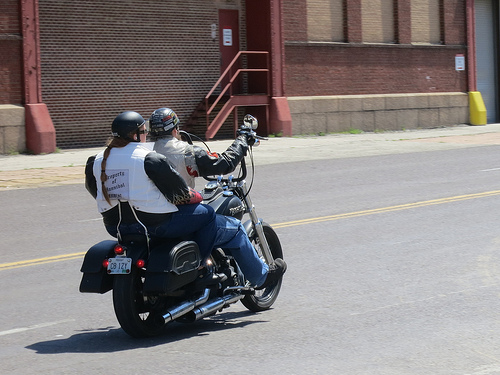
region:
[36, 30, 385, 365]
Two people on a motorcycle.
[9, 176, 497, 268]
Yellow line painted on street.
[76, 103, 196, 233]
A person with a long braid of hair.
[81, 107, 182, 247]
A person wearing a white vest.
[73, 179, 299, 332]
A black motorcycle.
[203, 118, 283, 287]
A pair of light colored jeans.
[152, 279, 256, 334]
Two silver mufflers on motorcycle.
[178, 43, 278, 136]
Set of stairs to building door.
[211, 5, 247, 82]
The door on the side of a building.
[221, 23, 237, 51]
White square sign on door.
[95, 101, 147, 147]
Woman with helmet on her head.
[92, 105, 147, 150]
Woman with black helmet on her head.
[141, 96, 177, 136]
Man with helmet on his head.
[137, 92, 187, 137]
Man with colorful helmet on his head.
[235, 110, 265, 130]
A man's hand with a glove on.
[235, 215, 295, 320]
A motorcycle tire on the street.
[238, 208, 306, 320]
A black motorcycle tire on the street.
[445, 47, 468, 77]
A sign on a building.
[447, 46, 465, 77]
A red and white sign on a building.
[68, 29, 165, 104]
A piece of a brick wall.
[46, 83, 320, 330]
two people on a black motorcycle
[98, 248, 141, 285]
a license plate on a motorcycle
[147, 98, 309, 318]
a man driving a motorcycle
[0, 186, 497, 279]
double yellow lines on the road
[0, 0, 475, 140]
a brick building on the left of the motorcyclists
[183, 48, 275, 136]
a staircase made of metal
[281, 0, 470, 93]
a rectangular sign on a brick building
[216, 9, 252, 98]
a red door with a rectangular sign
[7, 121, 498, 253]
a sidewalk next to the road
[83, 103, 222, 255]
two people wearing helmets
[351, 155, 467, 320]
a smooth grey street.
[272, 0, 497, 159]
a red brick building.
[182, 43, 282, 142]
a burgundy staircase.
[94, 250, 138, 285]
a white licence plate.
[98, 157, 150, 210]
a woman is wearing a white and black jacket.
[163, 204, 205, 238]
a woman is wearing blue jeans.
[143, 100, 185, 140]
a man is wearing a black yellow and red helmet.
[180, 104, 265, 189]
a man is wearing a black and red jacket.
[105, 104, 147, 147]
a woman is wearing a black helmet.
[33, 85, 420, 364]
a man is riding the woman on the motorcycle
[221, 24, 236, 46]
Delivery instructions posted on back door.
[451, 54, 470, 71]
No parking sign posted at delivery gate.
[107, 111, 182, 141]
Sun bouncing off black helmets.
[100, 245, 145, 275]
Three red lights and a license plate.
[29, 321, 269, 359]
Shadow under a motorcycle.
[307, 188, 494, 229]
Yellow street markings in middle of street.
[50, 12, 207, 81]
Red brick wall with white grout.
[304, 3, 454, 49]
Three bricked in windows.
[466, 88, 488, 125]
Yellow protection bumper for cars and trucks.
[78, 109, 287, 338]
Two people on a motocycle.